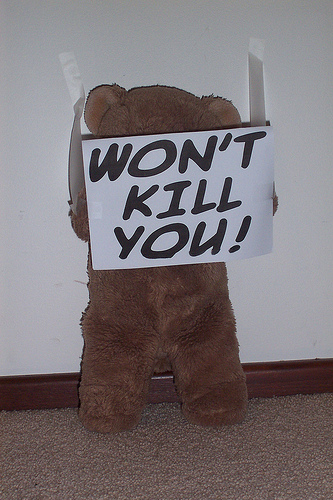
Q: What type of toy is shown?
A: Teddy bear.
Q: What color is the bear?
A: Brown.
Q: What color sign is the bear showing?
A: White.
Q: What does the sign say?
A: Won't Kill You.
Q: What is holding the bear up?
A: Tape.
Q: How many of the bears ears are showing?
A: Two.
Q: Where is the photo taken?
A: A bedroom.